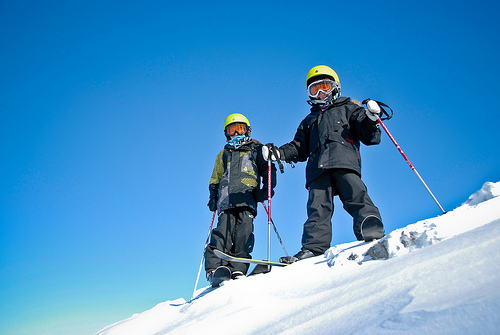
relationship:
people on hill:
[262, 65, 384, 265] [102, 183, 497, 333]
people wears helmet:
[267, 57, 400, 267] [299, 59, 342, 85]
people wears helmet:
[197, 103, 280, 293] [222, 106, 256, 130]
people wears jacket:
[262, 65, 384, 265] [279, 99, 389, 178]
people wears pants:
[262, 65, 384, 265] [297, 171, 389, 252]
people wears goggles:
[267, 57, 400, 267] [306, 71, 340, 100]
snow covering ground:
[94, 180, 484, 332] [89, 194, 484, 335]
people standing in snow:
[204, 112, 276, 287] [94, 180, 484, 332]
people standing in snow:
[262, 65, 384, 265] [94, 180, 484, 332]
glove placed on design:
[365, 100, 381, 122] [373, 113, 446, 214]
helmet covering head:
[303, 63, 342, 95] [303, 63, 339, 104]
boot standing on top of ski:
[293, 248, 316, 260] [210, 247, 300, 266]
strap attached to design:
[362, 98, 394, 125] [373, 113, 446, 214]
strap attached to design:
[373, 102, 390, 122] [373, 113, 446, 214]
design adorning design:
[375, 116, 415, 171] [373, 113, 446, 214]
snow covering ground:
[94, 180, 484, 332] [90, 194, 484, 331]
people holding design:
[262, 65, 384, 265] [373, 113, 446, 214]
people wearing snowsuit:
[262, 65, 384, 265] [279, 98, 382, 254]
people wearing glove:
[262, 65, 384, 265] [260, 143, 280, 163]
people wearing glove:
[262, 65, 384, 265] [363, 97, 382, 123]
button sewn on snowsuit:
[319, 162, 324, 166] [279, 98, 382, 254]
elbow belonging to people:
[290, 136, 310, 163] [262, 65, 384, 265]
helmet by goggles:
[306, 65, 342, 111] [303, 71, 346, 101]